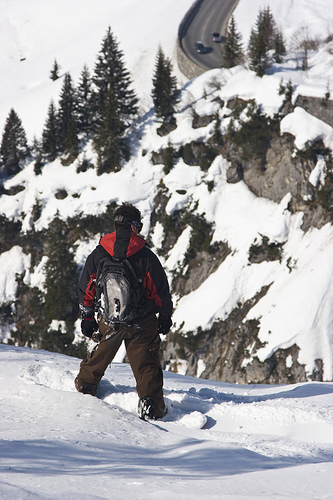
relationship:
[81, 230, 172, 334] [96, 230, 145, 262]
jacket has hood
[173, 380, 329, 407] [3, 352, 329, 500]
shadow on snow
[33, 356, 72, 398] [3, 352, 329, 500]
tracks in snow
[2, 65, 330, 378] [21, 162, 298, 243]
mountain covered in snow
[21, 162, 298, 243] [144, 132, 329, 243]
snow covered rock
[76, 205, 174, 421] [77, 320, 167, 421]
person wearing pants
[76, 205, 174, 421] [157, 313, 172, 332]
person wearing glove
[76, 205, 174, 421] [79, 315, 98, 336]
person wearing glove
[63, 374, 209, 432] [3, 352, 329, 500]
snowboard in snow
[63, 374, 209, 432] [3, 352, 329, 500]
snowboard covered in snow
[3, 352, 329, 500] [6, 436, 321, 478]
snow has shadows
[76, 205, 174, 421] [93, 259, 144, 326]
person has backpack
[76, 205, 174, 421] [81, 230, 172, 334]
person wearing jacket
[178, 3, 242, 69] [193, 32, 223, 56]
road has cars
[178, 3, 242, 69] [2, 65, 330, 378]
road below mountain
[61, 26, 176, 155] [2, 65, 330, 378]
trees on top of mountain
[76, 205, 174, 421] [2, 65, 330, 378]
person looking at mountain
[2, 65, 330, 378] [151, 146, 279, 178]
mountain has edges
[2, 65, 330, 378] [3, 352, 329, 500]
mountain covered in snow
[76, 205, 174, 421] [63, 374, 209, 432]
person on snowboard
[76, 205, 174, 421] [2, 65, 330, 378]
person on top of mountain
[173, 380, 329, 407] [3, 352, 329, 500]
shadow in snow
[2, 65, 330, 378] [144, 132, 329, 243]
mountain has rock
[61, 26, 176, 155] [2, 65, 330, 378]
trees on mountain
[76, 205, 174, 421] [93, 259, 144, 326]
person wearing backpack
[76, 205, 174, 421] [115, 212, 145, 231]
person wearing goggles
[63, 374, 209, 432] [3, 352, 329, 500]
snowboard on snow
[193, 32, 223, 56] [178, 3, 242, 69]
cars on road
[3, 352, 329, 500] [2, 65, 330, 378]
snow on mountain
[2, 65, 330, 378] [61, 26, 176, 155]
mountain has trees